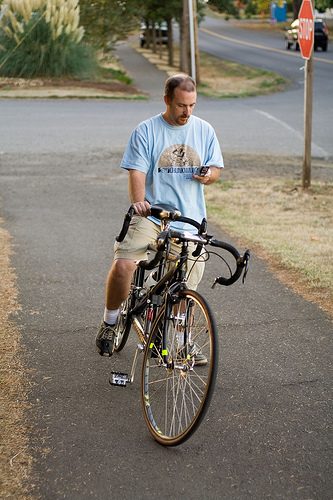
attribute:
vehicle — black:
[285, 14, 331, 57]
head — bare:
[162, 74, 196, 124]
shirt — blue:
[120, 110, 225, 232]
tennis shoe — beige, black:
[178, 340, 210, 364]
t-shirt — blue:
[117, 111, 225, 235]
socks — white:
[99, 296, 130, 333]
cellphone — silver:
[195, 164, 209, 185]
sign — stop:
[296, 0, 317, 191]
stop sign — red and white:
[298, 1, 314, 59]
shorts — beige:
[112, 211, 213, 291]